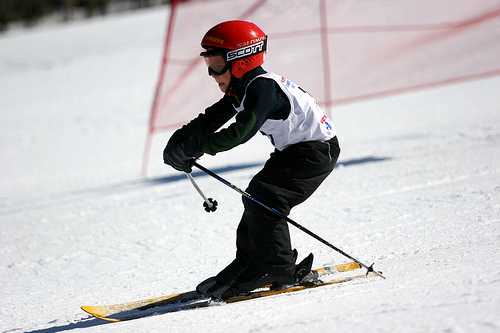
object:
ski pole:
[185, 149, 391, 288]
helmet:
[196, 19, 273, 83]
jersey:
[223, 73, 342, 154]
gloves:
[160, 116, 208, 176]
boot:
[226, 265, 301, 303]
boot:
[198, 254, 245, 289]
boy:
[156, 18, 353, 309]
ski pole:
[169, 161, 225, 221]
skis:
[65, 253, 382, 327]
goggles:
[193, 49, 272, 72]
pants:
[205, 131, 345, 295]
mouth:
[212, 78, 231, 89]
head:
[197, 20, 270, 96]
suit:
[149, 67, 348, 276]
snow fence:
[131, 1, 498, 150]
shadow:
[0, 279, 217, 333]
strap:
[225, 36, 275, 68]